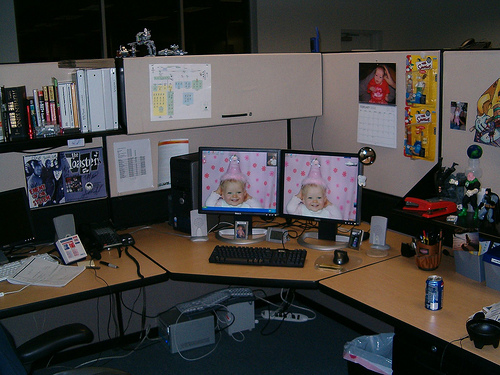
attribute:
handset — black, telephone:
[77, 222, 98, 254]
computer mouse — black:
[323, 240, 396, 311]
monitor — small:
[288, 136, 373, 219]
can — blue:
[423, 272, 444, 313]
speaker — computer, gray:
[189, 211, 208, 243]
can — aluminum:
[420, 269, 447, 317]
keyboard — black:
[204, 242, 307, 268]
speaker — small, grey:
[365, 212, 392, 252]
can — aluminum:
[400, 264, 465, 309]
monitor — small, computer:
[193, 141, 283, 227]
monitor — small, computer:
[278, 148, 363, 230]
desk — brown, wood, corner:
[23, 162, 497, 353]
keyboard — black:
[209, 243, 309, 269]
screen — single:
[280, 148, 360, 222]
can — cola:
[424, 273, 446, 315]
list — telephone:
[112, 136, 154, 193]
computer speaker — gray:
[364, 202, 401, 266]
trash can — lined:
[303, 313, 386, 373]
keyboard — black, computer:
[212, 245, 303, 265]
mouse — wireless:
[325, 243, 352, 269]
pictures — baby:
[202, 151, 352, 218]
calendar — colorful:
[356, 60, 401, 150]